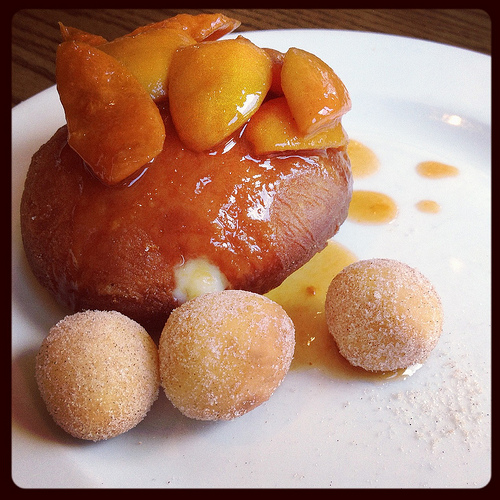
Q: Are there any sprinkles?
A: Yes, there are sprinkles.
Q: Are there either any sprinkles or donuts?
A: Yes, there are sprinkles.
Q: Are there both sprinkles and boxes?
A: No, there are sprinkles but no boxes.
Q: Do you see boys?
A: No, there are no boys.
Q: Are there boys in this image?
A: No, there are no boys.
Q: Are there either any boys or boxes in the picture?
A: No, there are no boys or boxes.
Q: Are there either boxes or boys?
A: No, there are no boys or boxes.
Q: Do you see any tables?
A: Yes, there is a table.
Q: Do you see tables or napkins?
A: Yes, there is a table.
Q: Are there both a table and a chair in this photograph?
A: No, there is a table but no chairs.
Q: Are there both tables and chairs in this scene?
A: No, there is a table but no chairs.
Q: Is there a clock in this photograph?
A: No, there are no clocks.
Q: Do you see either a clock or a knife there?
A: No, there are no clocks or knives.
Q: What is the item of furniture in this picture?
A: The piece of furniture is a table.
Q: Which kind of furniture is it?
A: The piece of furniture is a table.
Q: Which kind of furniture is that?
A: That is a table.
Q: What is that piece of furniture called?
A: That is a table.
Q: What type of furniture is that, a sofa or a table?
A: That is a table.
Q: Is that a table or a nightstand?
A: That is a table.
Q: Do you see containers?
A: No, there are no containers.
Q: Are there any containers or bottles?
A: No, there are no containers or bottles.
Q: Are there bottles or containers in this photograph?
A: No, there are no containers or bottles.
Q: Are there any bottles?
A: No, there are no bottles.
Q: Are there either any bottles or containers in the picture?
A: No, there are no bottles or containers.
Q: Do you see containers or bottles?
A: No, there are no bottles or containers.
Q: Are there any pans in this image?
A: No, there are no pans.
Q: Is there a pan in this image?
A: No, there are no pans.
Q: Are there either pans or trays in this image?
A: No, there are no pans or trays.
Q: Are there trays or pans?
A: No, there are no pans or trays.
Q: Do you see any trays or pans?
A: No, there are no pans or trays.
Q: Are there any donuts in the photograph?
A: Yes, there is a donut.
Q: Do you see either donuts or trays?
A: Yes, there is a donut.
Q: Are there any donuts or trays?
A: Yes, there is a donut.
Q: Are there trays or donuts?
A: Yes, there is a donut.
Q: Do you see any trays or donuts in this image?
A: Yes, there is a donut.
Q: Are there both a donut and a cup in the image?
A: No, there is a donut but no cups.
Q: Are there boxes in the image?
A: No, there are no boxes.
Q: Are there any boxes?
A: No, there are no boxes.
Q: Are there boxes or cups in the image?
A: No, there are no boxes or cups.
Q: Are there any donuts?
A: Yes, there are donuts.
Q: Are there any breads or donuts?
A: Yes, there are donuts.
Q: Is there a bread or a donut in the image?
A: Yes, there are donuts.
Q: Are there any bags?
A: No, there are no bags.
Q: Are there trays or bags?
A: No, there are no bags or trays.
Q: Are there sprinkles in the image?
A: Yes, there are sprinkles.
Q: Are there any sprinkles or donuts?
A: Yes, there are sprinkles.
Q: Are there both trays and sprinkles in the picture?
A: No, there are sprinkles but no trays.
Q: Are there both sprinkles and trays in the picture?
A: No, there are sprinkles but no trays.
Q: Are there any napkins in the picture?
A: No, there are no napkins.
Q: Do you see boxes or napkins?
A: No, there are no napkins or boxes.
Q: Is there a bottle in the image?
A: No, there are no bottles.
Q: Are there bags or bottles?
A: No, there are no bottles or bags.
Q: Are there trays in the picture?
A: No, there are no trays.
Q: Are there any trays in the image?
A: No, there are no trays.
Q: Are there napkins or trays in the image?
A: No, there are no trays or napkins.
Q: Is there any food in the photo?
A: Yes, there is food.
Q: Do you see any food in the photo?
A: Yes, there is food.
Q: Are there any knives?
A: No, there are no knives.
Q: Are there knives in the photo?
A: No, there are no knives.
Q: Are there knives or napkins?
A: No, there are no knives or napkins.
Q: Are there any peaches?
A: Yes, there are peaches.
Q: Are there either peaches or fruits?
A: Yes, there are peaches.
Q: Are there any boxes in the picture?
A: No, there are no boxes.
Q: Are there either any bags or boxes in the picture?
A: No, there are no boxes or bags.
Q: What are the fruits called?
A: The fruits are peaches.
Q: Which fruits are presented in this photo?
A: The fruits are peaches.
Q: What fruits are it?
A: The fruits are peaches.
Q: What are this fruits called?
A: These are peaches.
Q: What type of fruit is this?
A: These are peaches.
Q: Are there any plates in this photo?
A: Yes, there is a plate.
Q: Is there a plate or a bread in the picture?
A: Yes, there is a plate.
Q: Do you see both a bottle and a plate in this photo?
A: No, there is a plate but no bottles.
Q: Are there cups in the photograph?
A: No, there are no cups.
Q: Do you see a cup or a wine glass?
A: No, there are no cups or wine glasses.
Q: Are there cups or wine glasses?
A: No, there are no cups or wine glasses.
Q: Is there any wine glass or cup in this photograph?
A: No, there are no cups or wine glasses.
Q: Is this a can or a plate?
A: This is a plate.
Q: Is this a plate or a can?
A: This is a plate.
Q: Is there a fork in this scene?
A: No, there are no forks.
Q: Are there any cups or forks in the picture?
A: No, there are no forks or cups.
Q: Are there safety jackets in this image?
A: No, there are no safety jackets.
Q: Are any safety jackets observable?
A: No, there are no safety jackets.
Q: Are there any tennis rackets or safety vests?
A: No, there are no safety vests or tennis rackets.